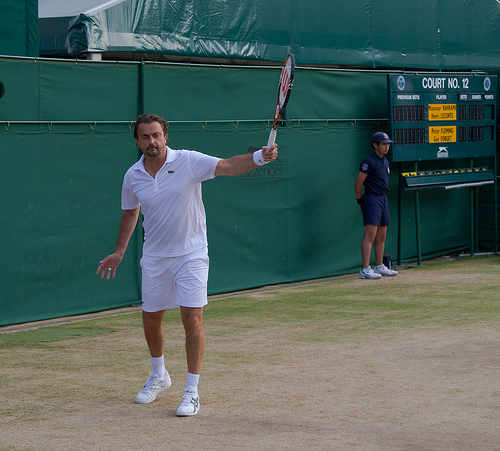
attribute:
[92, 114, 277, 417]
man — playing tennis, warming up, dressed in white, tennis player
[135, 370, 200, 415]
shoes — white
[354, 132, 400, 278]
man — dressed in blue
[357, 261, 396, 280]
shoes — white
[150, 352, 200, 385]
socks — white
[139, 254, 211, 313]
shorts — white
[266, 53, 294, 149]
racket — black, white, red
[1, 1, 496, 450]
court — faded green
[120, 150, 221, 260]
shirt — white, polo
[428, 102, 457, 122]
sign — yellow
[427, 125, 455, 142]
sign — yellow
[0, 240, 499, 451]
grass — dried, brown, green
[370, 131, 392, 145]
hat — blue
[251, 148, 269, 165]
wristband — white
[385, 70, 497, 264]
score board — green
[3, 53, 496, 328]
fence — green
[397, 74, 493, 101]
lettering — white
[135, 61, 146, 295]
pole — green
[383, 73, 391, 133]
pole — green